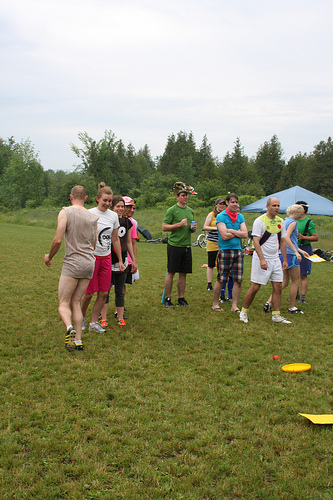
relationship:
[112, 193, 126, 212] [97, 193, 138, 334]
hair of lady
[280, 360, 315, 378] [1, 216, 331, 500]
frisbee on grass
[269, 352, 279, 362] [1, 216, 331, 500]
ball on grass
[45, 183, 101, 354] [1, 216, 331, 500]
person standing in grass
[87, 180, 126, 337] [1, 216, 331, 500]
person standing in grass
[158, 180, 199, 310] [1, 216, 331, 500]
person standing in grass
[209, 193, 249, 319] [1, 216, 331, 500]
person standing in grass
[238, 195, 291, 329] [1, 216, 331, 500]
person standing in grass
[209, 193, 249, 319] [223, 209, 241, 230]
man wearing scarf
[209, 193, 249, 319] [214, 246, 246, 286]
person wearing shorts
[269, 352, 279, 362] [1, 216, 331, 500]
ball laying on grass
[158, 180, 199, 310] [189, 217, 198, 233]
person holding can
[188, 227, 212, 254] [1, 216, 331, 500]
bicycle in grass